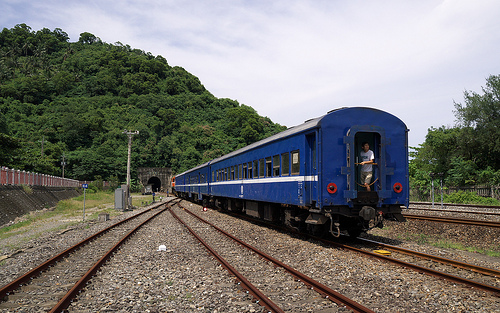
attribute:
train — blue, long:
[167, 103, 419, 239]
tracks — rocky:
[0, 186, 498, 312]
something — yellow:
[370, 245, 391, 256]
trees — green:
[0, 20, 301, 187]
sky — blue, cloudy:
[1, 1, 496, 169]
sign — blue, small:
[83, 184, 88, 187]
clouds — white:
[5, 0, 498, 145]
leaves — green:
[1, 23, 392, 196]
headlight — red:
[326, 181, 339, 194]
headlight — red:
[392, 182, 403, 193]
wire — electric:
[120, 125, 140, 138]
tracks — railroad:
[1, 195, 184, 312]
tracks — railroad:
[168, 195, 375, 312]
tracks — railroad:
[295, 213, 498, 308]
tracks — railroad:
[363, 208, 499, 233]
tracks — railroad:
[399, 199, 499, 220]